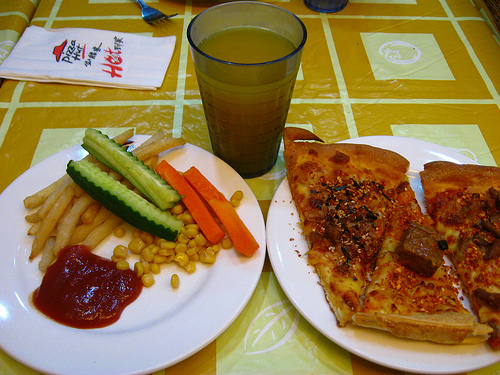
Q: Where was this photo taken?
A: Pizza Hut.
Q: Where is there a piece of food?
A: On a plate.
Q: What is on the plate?
A: Piece of food.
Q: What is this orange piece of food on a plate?
A: Carrot.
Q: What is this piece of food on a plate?
A: Pizza.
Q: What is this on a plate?
A: Piece of food.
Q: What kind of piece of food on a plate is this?
A: Pizza.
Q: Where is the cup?
A: On the table.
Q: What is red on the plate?
A: The ketchup.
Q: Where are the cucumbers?
A: On the plate.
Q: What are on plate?
A: Carrots.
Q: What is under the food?
A: White plate.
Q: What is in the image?
A: French fries.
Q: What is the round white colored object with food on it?
A: A plate.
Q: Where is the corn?
A: Under the carrots and cucumbers.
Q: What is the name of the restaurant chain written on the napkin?
A: Pizza Hut.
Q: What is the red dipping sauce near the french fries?
A: Ketchup.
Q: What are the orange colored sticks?
A: Carrots.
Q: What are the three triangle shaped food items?
A: Pizza.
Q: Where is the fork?
A: Next to the napkin.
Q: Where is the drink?
A: Between the plates.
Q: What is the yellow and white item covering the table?
A: A table cloth.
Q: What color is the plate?
A: White.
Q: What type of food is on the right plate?
A: Pizza.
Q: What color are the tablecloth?
A: Orange.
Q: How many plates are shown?
A: 2.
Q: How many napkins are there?
A: 1.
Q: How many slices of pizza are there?
A: 3.